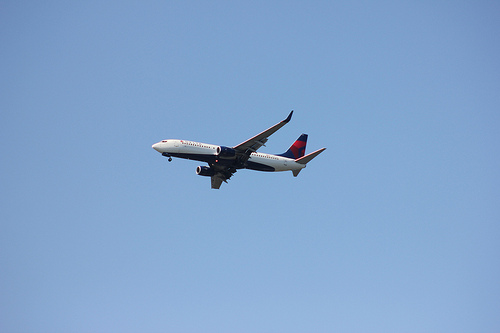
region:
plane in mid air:
[143, 100, 343, 202]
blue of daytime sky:
[369, 34, 461, 111]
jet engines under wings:
[192, 141, 245, 182]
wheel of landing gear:
[162, 153, 179, 168]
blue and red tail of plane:
[280, 129, 318, 161]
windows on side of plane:
[178, 142, 210, 150]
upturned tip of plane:
[275, 101, 300, 133]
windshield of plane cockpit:
[156, 136, 176, 149]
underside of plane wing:
[242, 134, 269, 154]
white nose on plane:
[145, 140, 170, 155]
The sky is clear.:
[338, 148, 450, 301]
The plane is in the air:
[130, 100, 325, 215]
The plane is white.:
[140, 93, 246, 150]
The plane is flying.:
[151, 109, 351, 211]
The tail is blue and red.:
[277, 129, 312, 156]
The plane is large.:
[131, 98, 366, 206]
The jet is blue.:
[212, 138, 232, 170]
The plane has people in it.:
[126, 78, 343, 220]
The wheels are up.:
[129, 98, 329, 223]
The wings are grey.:
[144, 109, 308, 214]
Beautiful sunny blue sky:
[0, 0, 498, 330]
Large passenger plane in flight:
[135, 101, 335, 201]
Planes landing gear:
[161, 150, 173, 160]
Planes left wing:
[226, 105, 297, 150]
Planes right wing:
[185, 160, 235, 192]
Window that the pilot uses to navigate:
[156, 135, 171, 145]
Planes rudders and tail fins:
[277, 130, 332, 180]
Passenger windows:
[180, 140, 220, 150]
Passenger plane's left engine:
[210, 140, 240, 160]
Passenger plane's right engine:
[191, 160, 221, 181]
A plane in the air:
[128, 102, 338, 199]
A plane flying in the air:
[122, 83, 343, 203]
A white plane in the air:
[129, 92, 334, 192]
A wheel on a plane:
[160, 151, 179, 166]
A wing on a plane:
[221, 98, 297, 147]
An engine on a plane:
[214, 140, 239, 165]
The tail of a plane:
[277, 130, 330, 180]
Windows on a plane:
[175, 137, 216, 149]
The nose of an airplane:
[140, 130, 180, 157]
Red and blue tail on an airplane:
[283, 127, 325, 182]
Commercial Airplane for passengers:
[147, 105, 357, 200]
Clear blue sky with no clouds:
[65, 212, 267, 283]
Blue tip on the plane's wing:
[230, 92, 307, 127]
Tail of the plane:
[287, 122, 332, 188]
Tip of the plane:
[117, 127, 197, 157]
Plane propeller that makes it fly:
[202, 132, 242, 157]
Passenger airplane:
[125, 97, 355, 209]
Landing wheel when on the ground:
[150, 155, 180, 165]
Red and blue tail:
[280, 130, 320, 155]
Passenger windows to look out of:
[175, 140, 213, 150]